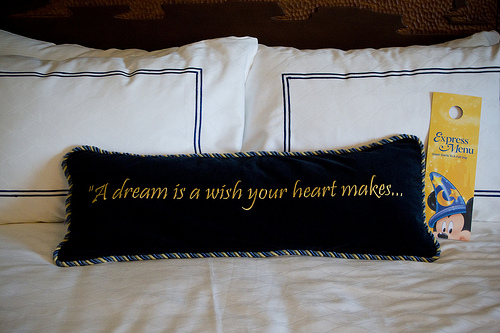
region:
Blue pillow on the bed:
[62, 138, 435, 280]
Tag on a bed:
[411, 75, 477, 246]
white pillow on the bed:
[258, 38, 497, 181]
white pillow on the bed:
[3, 17, 250, 229]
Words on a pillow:
[82, 162, 407, 216]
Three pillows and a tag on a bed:
[33, 35, 466, 281]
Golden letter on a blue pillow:
[82, 176, 107, 215]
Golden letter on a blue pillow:
[108, 171, 123, 203]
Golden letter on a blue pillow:
[124, 186, 128, 202]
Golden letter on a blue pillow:
[108, 176, 168, 208]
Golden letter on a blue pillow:
[165, 177, 185, 198]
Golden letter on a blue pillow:
[185, 180, 202, 207]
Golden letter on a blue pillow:
[201, 176, 239, 209]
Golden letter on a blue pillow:
[243, 183, 287, 212]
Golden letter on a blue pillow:
[290, 175, 338, 205]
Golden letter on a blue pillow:
[338, 177, 403, 209]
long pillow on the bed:
[25, 140, 472, 275]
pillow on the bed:
[5, 13, 261, 213]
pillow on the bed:
[254, 35, 496, 237]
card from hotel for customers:
[423, 83, 487, 241]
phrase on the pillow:
[71, 163, 411, 230]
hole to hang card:
[445, 90, 464, 129]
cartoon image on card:
[423, 165, 473, 237]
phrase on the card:
[431, 124, 471, 171]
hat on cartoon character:
[426, 165, 462, 217]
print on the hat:
[436, 175, 451, 206]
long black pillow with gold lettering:
[55, 137, 445, 279]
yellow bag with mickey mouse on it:
[413, 74, 485, 249]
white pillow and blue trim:
[22, 47, 227, 141]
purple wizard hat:
[425, 168, 475, 226]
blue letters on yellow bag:
[430, 120, 478, 165]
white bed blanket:
[172, 274, 311, 325]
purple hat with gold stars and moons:
[425, 166, 467, 229]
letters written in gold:
[85, 172, 408, 202]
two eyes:
[442, 220, 457, 237]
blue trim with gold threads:
[56, 254, 141, 272]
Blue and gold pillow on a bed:
[53, 133, 450, 282]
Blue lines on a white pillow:
[271, 66, 298, 148]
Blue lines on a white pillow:
[279, 65, 496, 80]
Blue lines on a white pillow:
[471, 181, 493, 212]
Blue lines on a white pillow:
[0, 66, 217, 86]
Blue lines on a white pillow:
[181, 58, 215, 149]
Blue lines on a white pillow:
[3, 179, 63, 210]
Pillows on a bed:
[18, 19, 492, 262]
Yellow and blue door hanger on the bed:
[424, 86, 481, 302]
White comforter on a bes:
[1, 214, 476, 329]